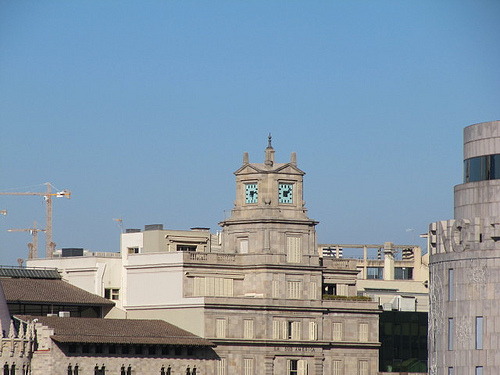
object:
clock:
[244, 182, 259, 204]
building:
[120, 134, 381, 375]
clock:
[278, 181, 294, 204]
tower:
[230, 130, 308, 218]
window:
[236, 235, 250, 255]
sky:
[0, 2, 500, 276]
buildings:
[426, 121, 499, 375]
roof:
[12, 314, 219, 349]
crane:
[0, 177, 74, 258]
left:
[0, 1, 252, 374]